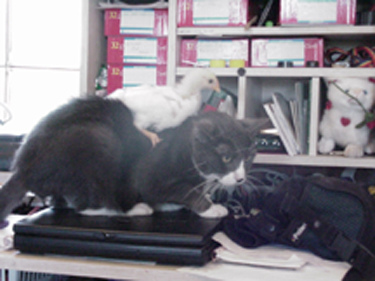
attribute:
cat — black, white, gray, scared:
[1, 94, 265, 232]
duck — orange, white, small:
[97, 67, 221, 151]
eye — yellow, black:
[220, 152, 234, 168]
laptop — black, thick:
[10, 196, 223, 264]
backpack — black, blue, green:
[228, 168, 375, 276]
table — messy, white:
[2, 210, 359, 281]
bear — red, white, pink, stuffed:
[317, 78, 375, 162]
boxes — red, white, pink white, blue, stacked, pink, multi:
[100, 8, 170, 38]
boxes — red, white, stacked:
[103, 33, 172, 67]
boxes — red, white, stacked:
[179, 37, 253, 73]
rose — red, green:
[331, 79, 375, 131]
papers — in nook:
[285, 79, 311, 158]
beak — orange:
[214, 85, 221, 93]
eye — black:
[206, 77, 214, 85]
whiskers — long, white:
[186, 172, 268, 201]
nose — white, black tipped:
[236, 176, 247, 186]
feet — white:
[200, 202, 228, 220]